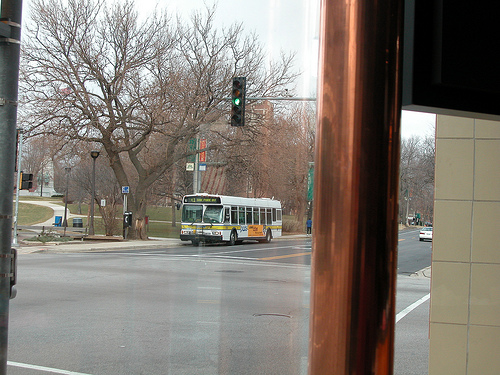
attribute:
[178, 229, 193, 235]
light — stop light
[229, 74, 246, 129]
stop sign — electronic, black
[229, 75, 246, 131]
traffic light — green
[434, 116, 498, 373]
tile wall — tan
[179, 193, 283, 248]
bus — large, white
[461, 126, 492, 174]
ground — green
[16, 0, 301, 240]
tree — bare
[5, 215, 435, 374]
pavement — gray, large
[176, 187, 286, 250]
bus — white, yellow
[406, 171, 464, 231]
ground — dormant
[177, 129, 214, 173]
banner — green, red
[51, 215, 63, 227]
trash can — small, blue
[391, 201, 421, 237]
ground — metal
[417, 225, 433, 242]
car — white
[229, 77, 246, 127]
light — light green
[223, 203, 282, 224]
windows — Lot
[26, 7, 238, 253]
tree — bare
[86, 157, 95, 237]
pole — black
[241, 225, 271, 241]
sign — orange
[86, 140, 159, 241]
street lamp — gray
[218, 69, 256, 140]
light — glowing